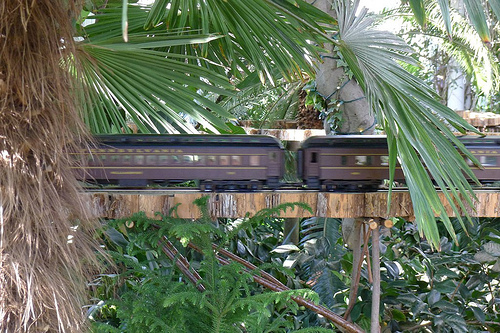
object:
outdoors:
[0, 0, 499, 332]